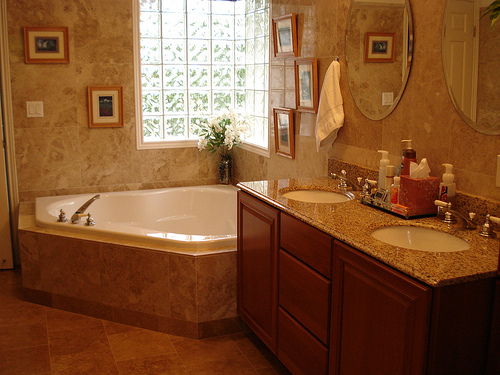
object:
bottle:
[437, 163, 457, 220]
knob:
[434, 200, 452, 208]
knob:
[490, 216, 500, 226]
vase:
[218, 154, 232, 185]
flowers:
[192, 109, 252, 155]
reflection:
[441, 4, 500, 136]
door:
[441, 0, 479, 124]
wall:
[0, 0, 232, 186]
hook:
[335, 56, 339, 62]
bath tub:
[17, 177, 237, 341]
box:
[398, 175, 440, 216]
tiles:
[28, 311, 178, 373]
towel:
[312, 58, 344, 156]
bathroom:
[1, 0, 500, 375]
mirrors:
[343, 1, 414, 120]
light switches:
[26, 101, 44, 118]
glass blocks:
[149, 9, 216, 86]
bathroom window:
[132, 0, 269, 150]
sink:
[278, 185, 356, 204]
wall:
[315, 0, 499, 231]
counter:
[237, 175, 500, 374]